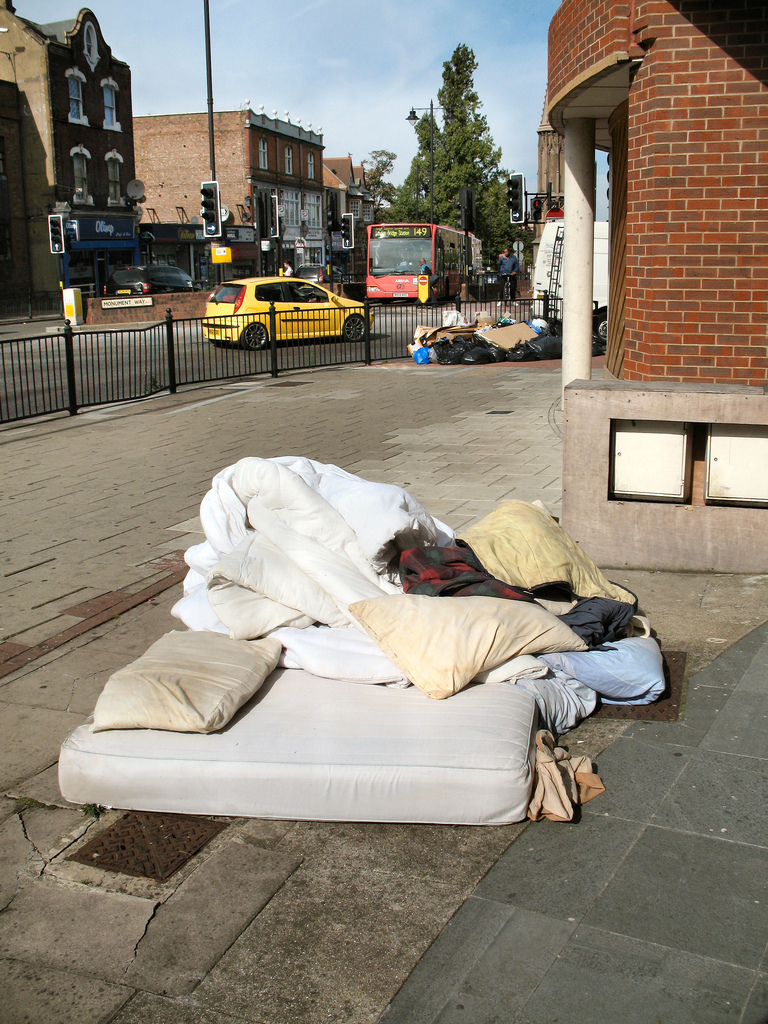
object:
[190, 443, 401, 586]
blankets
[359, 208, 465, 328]
bus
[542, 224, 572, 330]
ladder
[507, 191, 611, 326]
van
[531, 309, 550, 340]
garbage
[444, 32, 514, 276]
tree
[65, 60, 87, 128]
window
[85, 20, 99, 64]
window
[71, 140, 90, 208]
window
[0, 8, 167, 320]
building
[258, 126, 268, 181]
window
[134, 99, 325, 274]
building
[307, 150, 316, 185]
window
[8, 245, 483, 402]
street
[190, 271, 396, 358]
car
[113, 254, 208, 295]
car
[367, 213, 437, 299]
bus front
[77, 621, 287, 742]
pillow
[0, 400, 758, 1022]
street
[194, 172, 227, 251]
street light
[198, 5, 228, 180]
pole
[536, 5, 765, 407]
building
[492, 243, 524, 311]
man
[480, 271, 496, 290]
shirt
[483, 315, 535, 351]
trash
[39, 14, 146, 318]
store front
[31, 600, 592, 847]
mattress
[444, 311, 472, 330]
trash bags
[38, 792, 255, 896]
sewer drain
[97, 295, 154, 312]
sign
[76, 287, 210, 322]
wall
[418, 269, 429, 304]
sign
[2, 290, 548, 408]
fence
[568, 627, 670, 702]
covers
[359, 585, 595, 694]
pillows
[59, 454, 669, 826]
trash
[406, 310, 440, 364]
garbage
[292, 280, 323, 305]
cab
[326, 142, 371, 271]
building